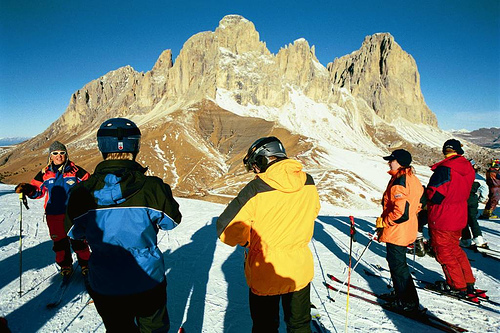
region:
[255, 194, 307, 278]
his jacket is yellow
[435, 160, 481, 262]
his outfit is red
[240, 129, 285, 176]
wearing a helmet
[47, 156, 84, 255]
her jacket is red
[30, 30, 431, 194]
mountain in the distance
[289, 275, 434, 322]
skis attached to their feet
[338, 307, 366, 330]
the snow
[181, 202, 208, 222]
the snow is white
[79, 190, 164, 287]
a black and blue jacket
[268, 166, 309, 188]
a yellow hood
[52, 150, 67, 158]
women wearing sunglasses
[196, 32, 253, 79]
the mountain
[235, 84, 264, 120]
snow on the mountain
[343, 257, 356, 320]
a ski pole in the snow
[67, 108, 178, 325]
skier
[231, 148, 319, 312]
skier in yellow jacket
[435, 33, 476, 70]
white clouds in blue sky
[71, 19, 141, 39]
white clouds in blue sky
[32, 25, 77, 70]
white clouds in blue sky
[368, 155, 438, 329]
skier with orange jacket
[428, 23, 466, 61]
white clouds in blue sky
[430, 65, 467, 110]
white clouds in blue sky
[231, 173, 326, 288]
black and yellow coat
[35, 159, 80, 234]
red and blue coat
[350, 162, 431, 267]
black and orange coat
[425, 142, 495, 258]
black and red coat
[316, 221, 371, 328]
yellow and orange pole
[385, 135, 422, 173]
woman has black hat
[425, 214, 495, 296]
man has red pants